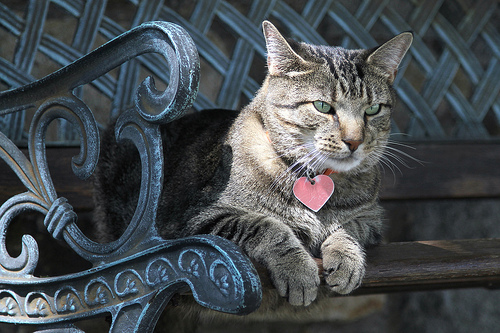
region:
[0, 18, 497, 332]
tabby cat lying on wood bench that has iron arm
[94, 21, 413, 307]
tabby cat wearing heart-shaped metal tag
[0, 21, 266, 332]
wrought-iron arm of bench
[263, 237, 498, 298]
front slat of bench under cat's paws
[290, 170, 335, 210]
red heart-shaped tag under cat's chin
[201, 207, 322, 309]
right front leg of tabby cat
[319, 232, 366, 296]
left front paw of tabby cat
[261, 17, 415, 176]
green eyes in cat's head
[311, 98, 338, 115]
cat's green eye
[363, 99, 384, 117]
cat's green eye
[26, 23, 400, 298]
Cat sitting on a bench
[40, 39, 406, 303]
Cat sitting in the sun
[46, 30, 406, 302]
Cat in the sun on a bench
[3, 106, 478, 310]
Bench is rot iron and wood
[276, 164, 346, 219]
Heart shaped tag on cat's collar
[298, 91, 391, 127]
Cat has green eyes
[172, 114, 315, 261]
Cat is calico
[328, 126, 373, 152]
Nose of cat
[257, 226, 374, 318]
Two of cats paws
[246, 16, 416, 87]
Cat has two ears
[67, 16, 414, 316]
a cat on a bench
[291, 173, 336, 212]
a heart shaped tag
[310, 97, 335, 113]
a cat's eye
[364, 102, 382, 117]
a cat's eye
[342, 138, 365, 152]
a cat's nose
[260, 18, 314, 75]
the ear of a cat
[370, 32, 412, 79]
the left ear of a cat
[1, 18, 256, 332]
metal siding of a bench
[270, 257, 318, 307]
right paw of a cat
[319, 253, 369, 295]
a cat's left paw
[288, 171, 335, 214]
heart shaped collar tag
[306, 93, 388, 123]
green cat eyes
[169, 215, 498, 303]
the bench seat is wooden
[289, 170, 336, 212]
the collar tag is red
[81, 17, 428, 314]
a grey colored cat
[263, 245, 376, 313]
the cats front paws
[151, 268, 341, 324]
the cat's tail is under the bench seat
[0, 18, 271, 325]
an iron arm rest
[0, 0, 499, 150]
the bench back is made of iron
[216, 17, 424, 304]
the light on the cat indicates morning sunlight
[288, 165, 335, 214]
a heart charm on the cat's neck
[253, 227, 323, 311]
the cat's right paw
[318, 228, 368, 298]
the cat's left paw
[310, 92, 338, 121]
the cat's right eye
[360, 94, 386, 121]
the cat's left eye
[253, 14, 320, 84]
the cat's right ear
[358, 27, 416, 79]
the cat's left ear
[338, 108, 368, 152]
the nose on the cat's face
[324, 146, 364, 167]
the mouth on the cat's face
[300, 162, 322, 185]
the loop connecting the heart to the cat's collar